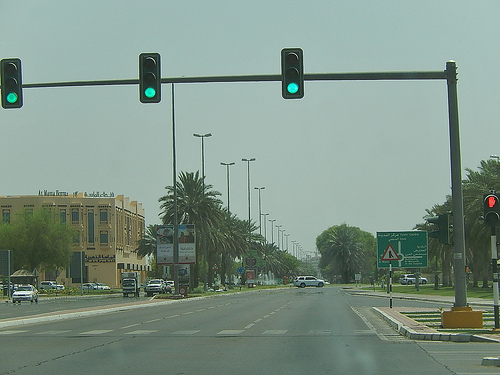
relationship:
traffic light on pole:
[481, 191, 499, 235] [487, 228, 499, 328]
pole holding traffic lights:
[445, 59, 467, 330] [279, 46, 305, 99]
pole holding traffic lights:
[445, 59, 467, 330] [138, 53, 162, 103]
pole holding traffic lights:
[445, 59, 467, 330] [0, 58, 21, 108]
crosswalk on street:
[0, 310, 385, 338] [190, 296, 359, 365]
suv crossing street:
[291, 274, 331, 292] [2, 281, 493, 373]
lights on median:
[190, 128, 316, 269] [0, 275, 285, 328]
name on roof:
[37, 186, 122, 200] [23, 179, 143, 219]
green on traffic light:
[282, 80, 297, 93] [280, 47, 308, 99]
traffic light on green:
[141, 53, 162, 100] [142, 87, 154, 97]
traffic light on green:
[1, 55, 22, 105] [7, 89, 17, 105]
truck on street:
[285, 269, 339, 294] [175, 297, 344, 343]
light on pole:
[7, 92, 17, 101] [445, 59, 467, 330]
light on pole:
[145, 87, 154, 95] [445, 59, 467, 330]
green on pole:
[282, 80, 297, 93] [445, 59, 467, 330]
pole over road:
[445, 59, 467, 330] [1, 285, 453, 374]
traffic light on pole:
[424, 205, 466, 259] [423, 81, 478, 331]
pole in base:
[445, 59, 467, 330] [434, 300, 484, 328]